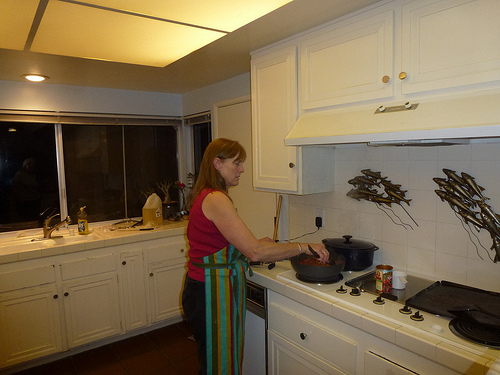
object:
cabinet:
[1, 233, 189, 372]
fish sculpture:
[432, 167, 500, 264]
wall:
[384, 215, 497, 272]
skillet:
[290, 249, 345, 284]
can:
[374, 263, 394, 294]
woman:
[180, 136, 332, 374]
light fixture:
[17, 67, 51, 85]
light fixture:
[0, 1, 291, 71]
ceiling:
[1, 1, 295, 68]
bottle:
[76, 206, 89, 235]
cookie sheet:
[403, 279, 499, 324]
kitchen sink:
[18, 229, 103, 252]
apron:
[202, 239, 248, 374]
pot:
[321, 233, 381, 273]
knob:
[336, 284, 348, 294]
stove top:
[277, 260, 498, 357]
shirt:
[187, 182, 229, 282]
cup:
[392, 270, 408, 290]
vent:
[367, 138, 471, 148]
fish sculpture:
[343, 166, 420, 230]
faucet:
[40, 207, 73, 239]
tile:
[409, 159, 438, 189]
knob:
[349, 286, 362, 296]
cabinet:
[248, 0, 499, 197]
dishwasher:
[240, 276, 268, 374]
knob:
[399, 303, 412, 315]